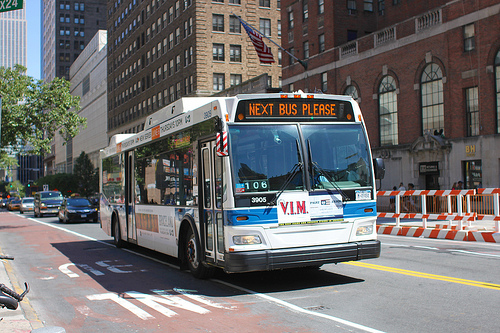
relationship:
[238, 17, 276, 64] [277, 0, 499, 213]
flag hanging from building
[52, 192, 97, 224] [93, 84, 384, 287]
car behind bus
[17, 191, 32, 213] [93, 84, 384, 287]
car behind bus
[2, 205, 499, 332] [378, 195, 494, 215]
street has a border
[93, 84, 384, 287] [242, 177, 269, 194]
bus has numbers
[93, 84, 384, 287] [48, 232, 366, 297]
bus has a shadow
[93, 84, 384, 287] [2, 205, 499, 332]
bus on street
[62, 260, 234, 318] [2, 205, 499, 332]
white text on street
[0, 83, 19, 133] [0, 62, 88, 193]
leaves on tree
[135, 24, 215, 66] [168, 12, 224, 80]
windows on building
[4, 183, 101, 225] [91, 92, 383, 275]
cars behind bus